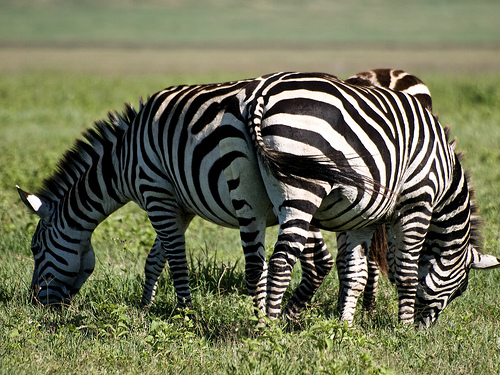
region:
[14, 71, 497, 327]
Zebras standing in the grass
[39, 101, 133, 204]
The mane of the zebra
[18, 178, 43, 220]
The left ear of the zebra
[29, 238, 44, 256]
The left eye of the zebra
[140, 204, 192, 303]
The front legs of the zebra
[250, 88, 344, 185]
The tail of the zebra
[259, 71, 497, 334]
The zebra is eating the grass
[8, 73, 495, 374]
A grass field below the zebra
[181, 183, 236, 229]
The stomach of the zebra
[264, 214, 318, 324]
The back leg of the zebra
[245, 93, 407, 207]
Zebra's tail in motion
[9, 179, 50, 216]
Zebra's black and white left ear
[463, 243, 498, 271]
Black and white zebra's ear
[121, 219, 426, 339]
Grouping of zebra legs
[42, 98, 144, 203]
Black and white striped mane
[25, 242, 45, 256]
Black zebra's eye looking towards the ground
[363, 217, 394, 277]
Black zebra's tail hanging down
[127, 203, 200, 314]
Zebra's two front legs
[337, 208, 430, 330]
Zebra's two front legs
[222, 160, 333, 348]
Zebra's black and white back legs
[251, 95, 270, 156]
black and white top of a zebra tale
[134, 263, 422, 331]
black and white striped legs of zebras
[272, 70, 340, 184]
black and white stripes on zebra's butt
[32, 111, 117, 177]
black and white striped zebra's mane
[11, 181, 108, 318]
zebra bent over eating grass and clover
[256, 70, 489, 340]
black and white zebra bent over eating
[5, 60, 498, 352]
three zebra eating green grass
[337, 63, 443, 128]
zebra standing behind another zebra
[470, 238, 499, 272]
black and white stripes of zebra's ear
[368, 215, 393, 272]
tail of zebra hidden behind other zebras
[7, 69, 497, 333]
Two zebras in the foreground.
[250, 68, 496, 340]
Black and white stripes on the zebra.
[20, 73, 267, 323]
Zebra eating the grass.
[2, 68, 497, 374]
Grass in the forefront.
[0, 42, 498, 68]
Dirt road in the background.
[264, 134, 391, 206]
Back tail on the zebra.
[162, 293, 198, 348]
Weed in the grass.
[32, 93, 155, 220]
Black and white mane on the zebra.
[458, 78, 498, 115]
Small green bush in the background.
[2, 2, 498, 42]
Dark green grass in the background.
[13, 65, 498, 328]
two zebras in the wild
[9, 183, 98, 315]
the head of a zebra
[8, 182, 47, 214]
the ear of a zebra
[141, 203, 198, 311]
the front legs of a zebra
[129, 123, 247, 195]
the stripes of a zebra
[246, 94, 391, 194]
the tail of a zebra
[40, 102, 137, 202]
the main of a zebra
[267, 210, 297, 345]
the back leg of a zebra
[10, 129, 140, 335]
a zebra eating grass